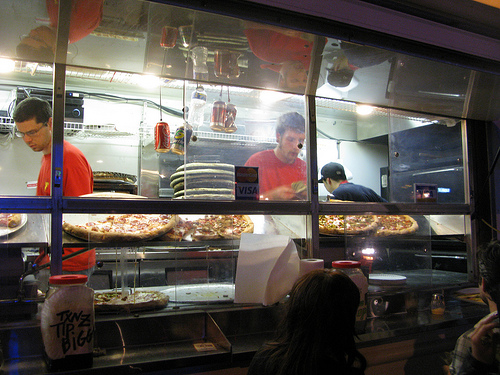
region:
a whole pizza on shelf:
[60, 185, 175, 242]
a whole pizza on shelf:
[166, 204, 253, 244]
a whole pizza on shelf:
[316, 196, 382, 235]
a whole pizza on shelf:
[374, 204, 416, 236]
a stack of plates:
[171, 161, 233, 201]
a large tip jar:
[36, 273, 107, 373]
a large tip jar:
[327, 256, 372, 333]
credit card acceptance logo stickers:
[231, 163, 261, 203]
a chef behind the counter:
[10, 96, 94, 197]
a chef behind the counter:
[231, 107, 318, 204]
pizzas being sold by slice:
[62, 186, 371, 239]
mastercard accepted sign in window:
[230, 160, 261, 183]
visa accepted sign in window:
[236, 186, 265, 200]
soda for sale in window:
[151, 107, 200, 166]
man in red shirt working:
[10, 93, 119, 228]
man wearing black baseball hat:
[316, 160, 343, 196]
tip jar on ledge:
[26, 259, 106, 366]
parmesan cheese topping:
[419, 284, 449, 324]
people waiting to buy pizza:
[246, 257, 493, 358]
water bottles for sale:
[187, 82, 209, 135]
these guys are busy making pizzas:
[13, 20, 493, 361]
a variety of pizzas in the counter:
[8, 172, 448, 269]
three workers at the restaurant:
[10, 76, 421, 197]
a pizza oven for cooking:
[368, 106, 483, 232]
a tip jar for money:
[23, 256, 143, 373]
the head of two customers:
[241, 211, 498, 357]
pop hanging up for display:
[119, 66, 269, 175]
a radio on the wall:
[0, 75, 107, 155]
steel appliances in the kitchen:
[10, 68, 423, 193]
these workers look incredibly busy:
[17, 88, 321, 190]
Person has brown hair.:
[277, 109, 305, 196]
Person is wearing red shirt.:
[255, 149, 300, 226]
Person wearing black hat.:
[327, 162, 332, 170]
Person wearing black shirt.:
[335, 180, 377, 223]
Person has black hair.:
[273, 286, 335, 361]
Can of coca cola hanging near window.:
[138, 122, 177, 187]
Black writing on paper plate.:
[40, 287, 107, 372]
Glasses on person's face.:
[12, 120, 64, 152]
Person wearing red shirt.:
[45, 152, 102, 213]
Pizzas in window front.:
[56, 167, 276, 267]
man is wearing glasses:
[7, 107, 66, 159]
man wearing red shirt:
[29, 151, 96, 303]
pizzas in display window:
[1, 168, 469, 253]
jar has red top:
[42, 270, 99, 297]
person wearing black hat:
[315, 154, 349, 194]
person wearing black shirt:
[323, 183, 375, 213]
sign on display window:
[235, 159, 269, 206]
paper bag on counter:
[207, 207, 307, 319]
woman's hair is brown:
[255, 256, 392, 370]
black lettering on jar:
[48, 294, 95, 359]